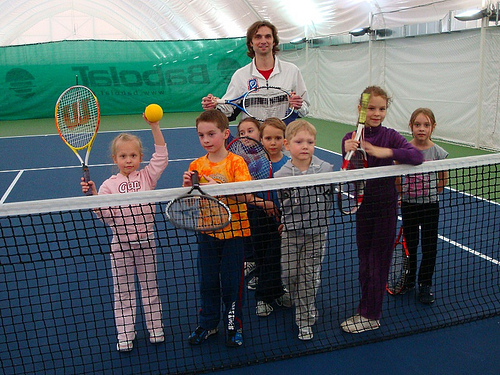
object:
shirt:
[187, 151, 253, 239]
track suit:
[341, 122, 424, 320]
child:
[81, 103, 169, 352]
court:
[3, 114, 500, 374]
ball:
[143, 102, 164, 122]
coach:
[199, 21, 308, 143]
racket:
[54, 83, 102, 198]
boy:
[183, 107, 251, 341]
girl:
[339, 84, 424, 335]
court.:
[0, 110, 500, 375]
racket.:
[165, 170, 233, 233]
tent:
[0, 36, 277, 122]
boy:
[279, 118, 332, 340]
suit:
[91, 143, 169, 343]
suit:
[275, 155, 338, 326]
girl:
[401, 106, 445, 300]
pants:
[401, 201, 440, 294]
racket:
[385, 229, 409, 295]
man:
[200, 25, 307, 121]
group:
[78, 19, 452, 355]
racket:
[211, 85, 293, 123]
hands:
[286, 90, 301, 109]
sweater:
[96, 149, 170, 240]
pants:
[111, 232, 163, 341]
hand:
[143, 111, 164, 126]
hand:
[78, 176, 99, 194]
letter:
[63, 97, 92, 129]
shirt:
[342, 127, 424, 198]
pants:
[354, 193, 394, 317]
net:
[0, 153, 498, 374]